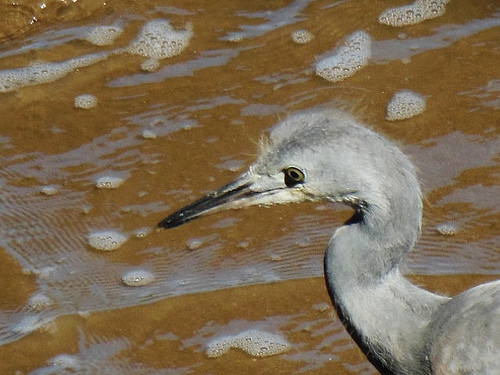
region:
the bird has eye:
[211, 93, 358, 278]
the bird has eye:
[198, 84, 419, 361]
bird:
[187, 113, 452, 347]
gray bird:
[156, 106, 467, 351]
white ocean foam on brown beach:
[17, 289, 199, 366]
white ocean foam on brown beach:
[169, 278, 314, 356]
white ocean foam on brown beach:
[18, 181, 126, 308]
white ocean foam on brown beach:
[22, 93, 114, 206]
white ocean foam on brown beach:
[20, 26, 210, 138]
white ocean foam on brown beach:
[136, 31, 223, 181]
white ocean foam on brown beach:
[214, 18, 336, 85]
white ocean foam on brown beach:
[367, 48, 474, 110]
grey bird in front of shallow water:
[77, 58, 484, 368]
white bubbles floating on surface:
[55, 20, 435, 301]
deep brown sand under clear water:
[40, 60, 150, 345]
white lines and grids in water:
[7, 166, 128, 331]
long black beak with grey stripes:
[131, 150, 267, 240]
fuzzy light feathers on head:
[250, 81, 425, 207]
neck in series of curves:
[270, 85, 460, 355]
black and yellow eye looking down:
[265, 150, 315, 200]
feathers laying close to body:
[320, 251, 492, 366]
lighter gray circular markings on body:
[401, 302, 494, 372]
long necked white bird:
[133, 67, 498, 370]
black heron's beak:
[150, 167, 267, 248]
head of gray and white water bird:
[142, 100, 436, 266]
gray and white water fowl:
[133, 81, 495, 371]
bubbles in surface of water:
[113, 11, 188, 68]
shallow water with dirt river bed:
[8, 15, 243, 162]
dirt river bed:
[134, 309, 220, 364]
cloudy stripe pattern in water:
[9, 140, 144, 335]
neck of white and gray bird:
[301, 202, 451, 372]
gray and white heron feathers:
[422, 276, 499, 371]